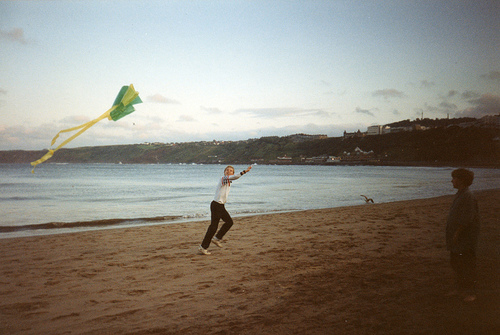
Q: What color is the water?
A: Gray and blue.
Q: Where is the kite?
A: In the sky.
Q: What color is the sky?
A: Blue.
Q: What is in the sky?
A: The kite.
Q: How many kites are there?
A: One.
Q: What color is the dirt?
A: Brown.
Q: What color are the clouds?
A: Gray.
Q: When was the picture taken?
A: Daytime.